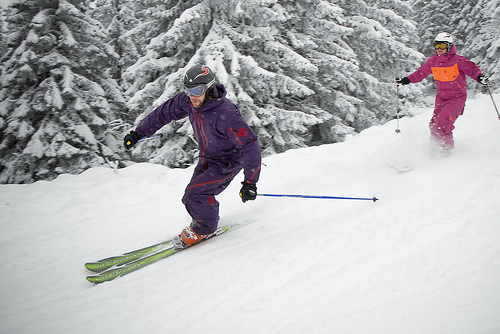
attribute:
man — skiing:
[124, 64, 261, 251]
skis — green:
[85, 223, 236, 283]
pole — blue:
[239, 193, 379, 202]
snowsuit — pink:
[406, 44, 481, 153]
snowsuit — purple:
[135, 83, 261, 236]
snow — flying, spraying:
[393, 112, 458, 174]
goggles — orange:
[431, 41, 453, 49]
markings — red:
[194, 65, 210, 83]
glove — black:
[239, 182, 258, 203]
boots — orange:
[171, 226, 220, 251]